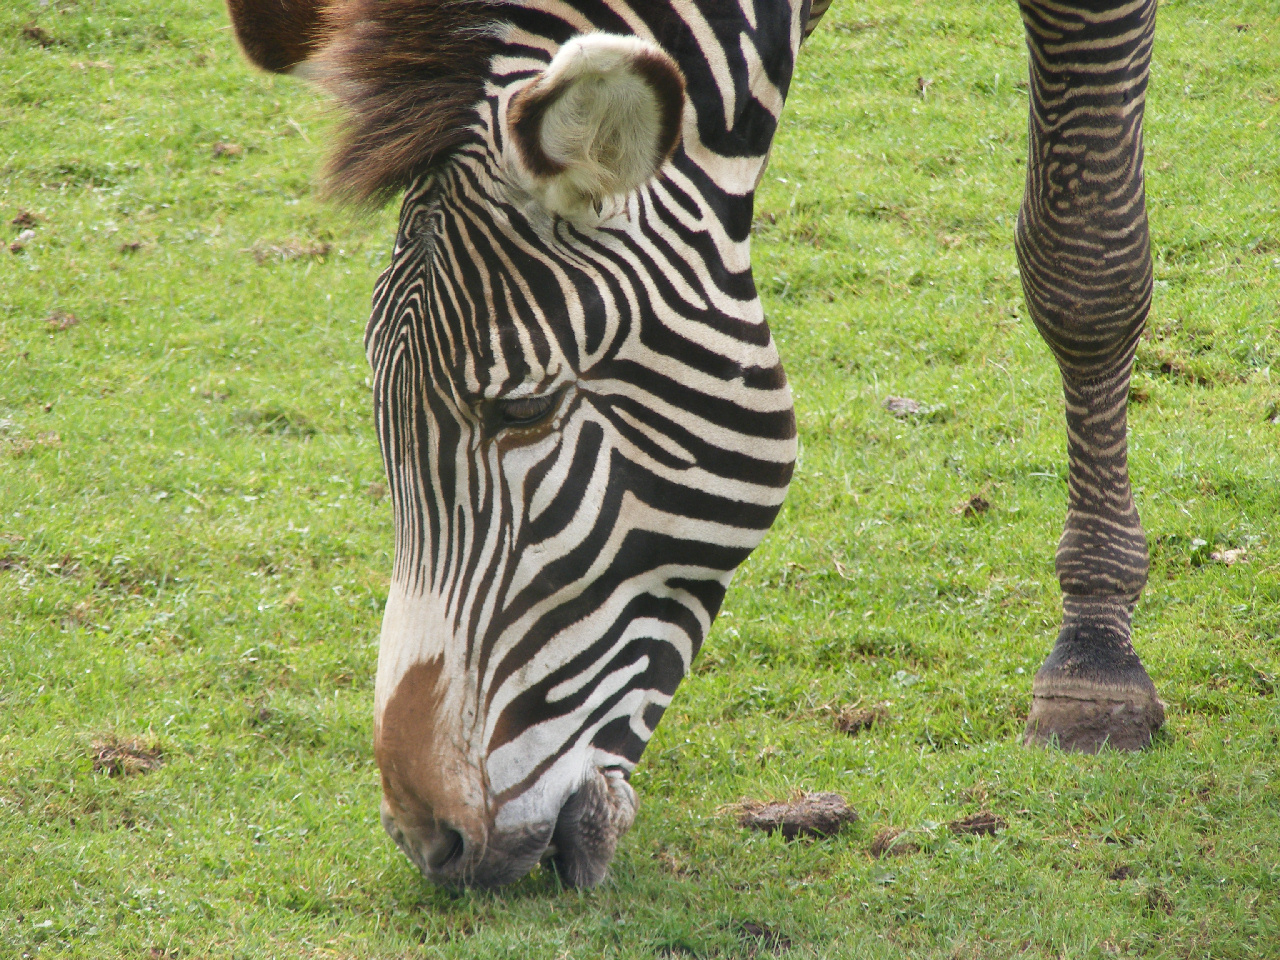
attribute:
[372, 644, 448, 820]
spot — brown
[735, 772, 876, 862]
grass — brown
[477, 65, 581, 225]
ear — brown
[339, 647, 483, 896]
nose — brown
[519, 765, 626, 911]
mouth — black and brown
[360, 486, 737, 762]
face — black and white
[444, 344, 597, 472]
eye — dark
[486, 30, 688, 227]
ear — white and black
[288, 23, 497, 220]
mane — dark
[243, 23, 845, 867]
zebra — standing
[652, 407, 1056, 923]
grass — green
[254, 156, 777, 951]
zebra — striped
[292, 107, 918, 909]
zebra — bending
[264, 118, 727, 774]
face — black and white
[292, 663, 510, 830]
nose — brown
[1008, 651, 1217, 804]
hoof — grey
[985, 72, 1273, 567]
leg — brown, black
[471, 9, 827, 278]
ear — black, white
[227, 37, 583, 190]
mane — white, black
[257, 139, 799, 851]
zebra — black, white, grazing